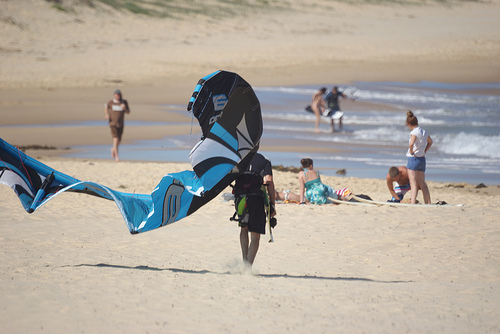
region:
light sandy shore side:
[0, 0, 499, 332]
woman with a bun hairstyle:
[402, 108, 435, 204]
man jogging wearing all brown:
[102, 88, 131, 161]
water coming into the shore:
[3, 78, 498, 185]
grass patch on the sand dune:
[45, 0, 316, 20]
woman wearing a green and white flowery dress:
[295, 155, 337, 202]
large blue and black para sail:
[0, 68, 264, 234]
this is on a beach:
[12, 24, 463, 304]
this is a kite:
[72, 73, 264, 233]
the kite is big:
[31, 71, 281, 226]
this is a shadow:
[60, 225, 431, 327]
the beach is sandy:
[77, 245, 384, 332]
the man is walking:
[141, 223, 401, 328]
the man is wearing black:
[207, 127, 298, 248]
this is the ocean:
[318, 70, 463, 171]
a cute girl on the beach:
[397, 108, 437, 202]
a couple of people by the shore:
[300, 71, 360, 142]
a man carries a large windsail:
[3, 65, 285, 265]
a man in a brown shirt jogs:
[95, 80, 140, 165]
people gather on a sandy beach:
[265, 70, 446, 222]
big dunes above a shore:
[27, 5, 498, 96]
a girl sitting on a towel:
[296, 151, 348, 208]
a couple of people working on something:
[379, 108, 441, 208]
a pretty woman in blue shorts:
[403, 104, 440, 208]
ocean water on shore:
[17, 82, 499, 177]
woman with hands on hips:
[404, 110, 434, 203]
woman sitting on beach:
[298, 156, 336, 203]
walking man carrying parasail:
[0, 68, 275, 269]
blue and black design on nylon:
[0, 67, 260, 227]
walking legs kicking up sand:
[227, 230, 262, 276]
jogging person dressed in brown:
[101, 87, 126, 157]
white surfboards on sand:
[330, 195, 462, 208]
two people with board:
[307, 86, 354, 132]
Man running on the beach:
[103, 89, 132, 161]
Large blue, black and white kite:
[1, 67, 263, 234]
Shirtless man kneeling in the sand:
[383, 165, 415, 204]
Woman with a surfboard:
[308, 86, 326, 129]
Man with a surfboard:
[325, 85, 350, 130]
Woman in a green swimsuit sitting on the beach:
[297, 155, 330, 204]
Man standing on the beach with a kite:
[227, 138, 277, 273]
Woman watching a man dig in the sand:
[403, 110, 433, 207]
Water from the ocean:
[3, 75, 498, 190]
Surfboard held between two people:
[300, 105, 343, 121]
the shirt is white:
[402, 130, 429, 165]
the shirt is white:
[407, 130, 429, 160]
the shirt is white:
[399, 123, 424, 165]